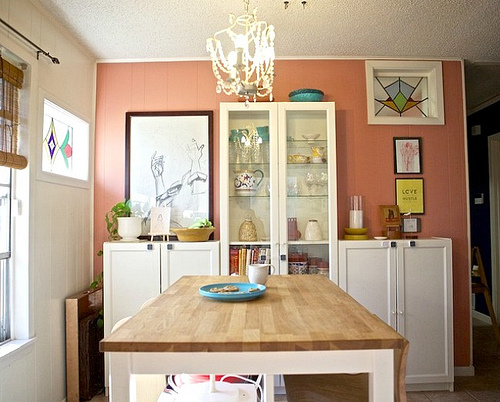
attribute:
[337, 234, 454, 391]
cabinet — short, white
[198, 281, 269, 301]
plate — round, blue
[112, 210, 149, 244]
vase — white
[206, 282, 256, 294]
cookies — baked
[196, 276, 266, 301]
plate — blue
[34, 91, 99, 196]
window — inset, stained glass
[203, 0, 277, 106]
chandelier — white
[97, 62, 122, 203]
wall — painted, peach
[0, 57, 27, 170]
blinds — bamboo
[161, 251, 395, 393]
table — butcher block, kitchen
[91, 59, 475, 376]
wall — peach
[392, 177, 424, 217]
print — small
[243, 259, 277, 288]
mug — white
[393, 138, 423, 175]
print — small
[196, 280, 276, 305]
blue plate — round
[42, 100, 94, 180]
window — stained, glass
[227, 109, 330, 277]
windows — glass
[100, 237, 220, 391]
cabinet — white, short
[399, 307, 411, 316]
knob — white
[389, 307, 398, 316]
knob — white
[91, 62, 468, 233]
room peach — white, turquoise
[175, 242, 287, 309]
plate — blue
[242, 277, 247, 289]
plate — blue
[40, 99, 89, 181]
window — stained, glass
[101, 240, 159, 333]
cabinet — white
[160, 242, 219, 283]
cabinet — white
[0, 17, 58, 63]
rod — black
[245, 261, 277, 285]
cup — white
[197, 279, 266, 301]
plate — blue, round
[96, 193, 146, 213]
plant — green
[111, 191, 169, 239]
pot — white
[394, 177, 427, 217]
picture — yellow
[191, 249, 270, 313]
plate — round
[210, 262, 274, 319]
bowl — blue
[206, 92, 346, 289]
curio cabinet — glass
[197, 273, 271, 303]
plate — blue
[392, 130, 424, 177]
print — small